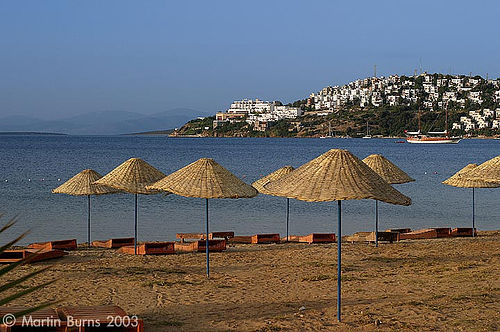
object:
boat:
[404, 103, 463, 144]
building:
[227, 97, 301, 121]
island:
[165, 72, 500, 138]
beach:
[1, 258, 500, 332]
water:
[1, 136, 500, 225]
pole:
[335, 198, 343, 324]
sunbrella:
[144, 156, 259, 201]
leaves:
[1, 226, 30, 253]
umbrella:
[261, 146, 413, 207]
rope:
[0, 179, 66, 182]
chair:
[3, 247, 64, 263]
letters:
[20, 315, 102, 330]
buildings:
[447, 121, 463, 134]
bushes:
[380, 109, 455, 136]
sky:
[1, 4, 499, 106]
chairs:
[452, 225, 476, 236]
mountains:
[1, 105, 221, 135]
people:
[393, 140, 406, 144]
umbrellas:
[50, 167, 122, 196]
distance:
[1, 100, 219, 136]